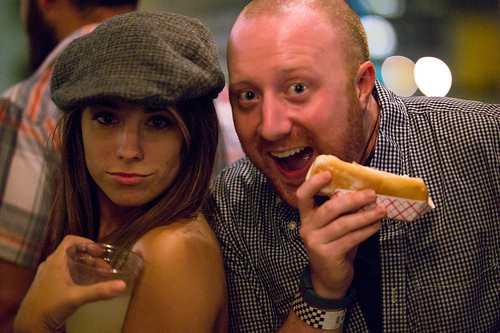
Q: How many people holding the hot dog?
A: One.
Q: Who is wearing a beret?
A: A woman.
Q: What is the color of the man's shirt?
A: Black.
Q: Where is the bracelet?
A: On man's wrist.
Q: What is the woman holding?
A: A cup.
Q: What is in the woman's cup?
A: Juice.